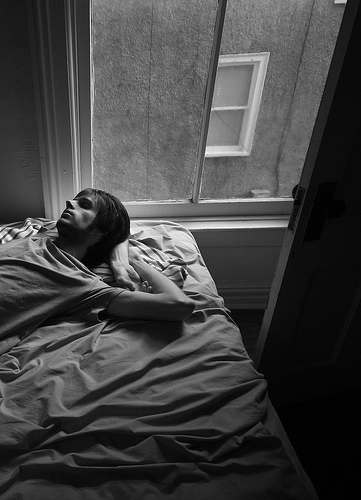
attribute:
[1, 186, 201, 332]
guy — laying down, lying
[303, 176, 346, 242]
handle — dark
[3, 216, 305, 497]
sheets — crumpled, wrinkled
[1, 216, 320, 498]
bed — inside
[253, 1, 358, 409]
door — wooden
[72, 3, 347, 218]
window — open, white, large, glass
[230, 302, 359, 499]
floor — wooden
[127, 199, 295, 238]
ledge — white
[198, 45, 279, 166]
window — white